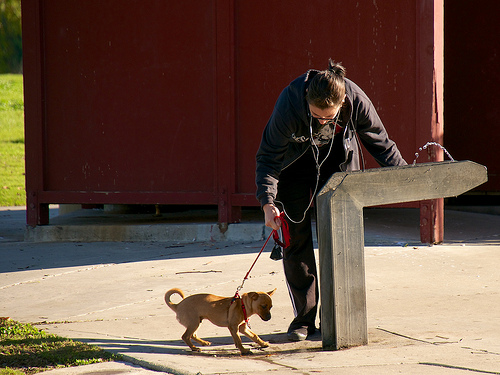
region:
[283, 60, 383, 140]
the head of a woman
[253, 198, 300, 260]
the hand of a woman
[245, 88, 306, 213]
the arm of a woman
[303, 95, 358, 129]
the eyes of a woman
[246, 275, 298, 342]
the head of a dog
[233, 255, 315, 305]
the ears of a dog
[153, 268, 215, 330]
the tail of a dog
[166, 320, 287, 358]
the legs of a dog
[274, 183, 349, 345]
the leg of a woman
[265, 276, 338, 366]
the foot of a woman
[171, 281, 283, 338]
small brown colored dog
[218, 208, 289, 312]
hand holding red leash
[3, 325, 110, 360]
small green and dirt patch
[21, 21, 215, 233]
large red colored building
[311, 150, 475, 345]
steel water fountain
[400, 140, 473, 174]
water coming out in arch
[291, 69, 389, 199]
lady is bending over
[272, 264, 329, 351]
lady wearing jeans and shoes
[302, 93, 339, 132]
lady is wearing sunglasses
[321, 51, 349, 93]
ladies hair is in a ponytail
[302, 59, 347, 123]
s woman with brown hair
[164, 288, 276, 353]
a brown Chihuahua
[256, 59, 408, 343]
a woman bending toward a dog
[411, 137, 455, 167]
water spurting from a water fountain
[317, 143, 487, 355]
a water fountain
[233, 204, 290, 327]
a woman holding a red leash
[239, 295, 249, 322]
dog wearing a red collar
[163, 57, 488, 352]
a woman and a dog by a water fountain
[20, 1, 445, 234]
a red wooden wall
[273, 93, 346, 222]
white wires connected to earbuds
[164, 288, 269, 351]
small brown dog on top of pavement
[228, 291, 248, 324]
dog wearing a red harness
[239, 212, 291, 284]
red leash attached to harness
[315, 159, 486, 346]
dog next to a water fountain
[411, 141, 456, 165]
water above water fountain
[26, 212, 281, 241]
cement foundation under red wall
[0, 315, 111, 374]
grass next to pavement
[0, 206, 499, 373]
pavement is gray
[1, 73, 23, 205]
grass behind wall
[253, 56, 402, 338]
woman is bending over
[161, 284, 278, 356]
Brown dog standing next to a post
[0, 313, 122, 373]
Green grass near the pavement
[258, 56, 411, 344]
Woman standing next to the post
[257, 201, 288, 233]
Woman's hand holding a red tie connected to the dog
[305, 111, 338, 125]
Black glasses worn by the woman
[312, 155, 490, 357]
Brown post next to the woman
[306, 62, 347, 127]
Woman's face looking downward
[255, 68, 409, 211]
Black jacket worn by woman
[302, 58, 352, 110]
Woman's hair with ponytail hair style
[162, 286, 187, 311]
Curved brown tail of a dog